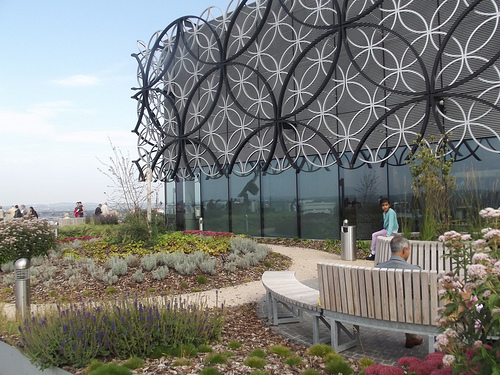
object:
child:
[365, 197, 399, 261]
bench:
[315, 262, 465, 327]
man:
[370, 235, 430, 298]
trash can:
[341, 219, 357, 262]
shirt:
[383, 208, 399, 238]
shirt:
[373, 255, 421, 298]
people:
[0, 204, 38, 219]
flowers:
[0, 215, 56, 261]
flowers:
[180, 230, 237, 238]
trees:
[97, 135, 163, 242]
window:
[261, 157, 296, 238]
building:
[131, 0, 499, 238]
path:
[1, 238, 337, 326]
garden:
[1, 203, 500, 375]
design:
[130, 1, 499, 182]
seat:
[258, 261, 461, 367]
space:
[0, 0, 500, 375]